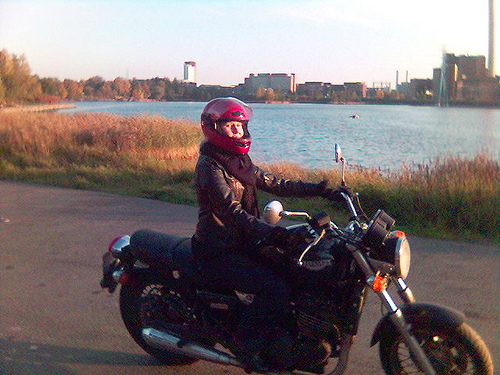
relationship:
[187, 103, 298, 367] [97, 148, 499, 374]
person on motorcycle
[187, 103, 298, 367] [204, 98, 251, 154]
person wears helmet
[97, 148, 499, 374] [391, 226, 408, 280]
motorcycle has headlight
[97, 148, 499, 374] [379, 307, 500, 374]
motorcycle has front tire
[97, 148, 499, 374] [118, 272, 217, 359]
motorcycle has rear tire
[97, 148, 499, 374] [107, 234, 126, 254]
motorcycle has brake light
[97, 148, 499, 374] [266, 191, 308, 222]
motorcycle has mirror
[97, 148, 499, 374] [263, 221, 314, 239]
motorcycle has handlebars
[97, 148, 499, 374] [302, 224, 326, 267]
motorcycle has turn signal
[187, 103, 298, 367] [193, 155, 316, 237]
person wears jacket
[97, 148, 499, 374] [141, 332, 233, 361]
motorcycle has exhaust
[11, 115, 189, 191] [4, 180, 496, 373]
grass near road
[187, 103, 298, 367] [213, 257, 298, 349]
person wears jeans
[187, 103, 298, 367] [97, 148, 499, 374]
person rides motorcycle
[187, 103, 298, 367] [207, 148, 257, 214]
person wears scarf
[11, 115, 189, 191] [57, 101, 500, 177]
grass near lake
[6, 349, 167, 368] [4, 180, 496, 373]
shadow on road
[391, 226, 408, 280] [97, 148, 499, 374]
headlight on motorcycle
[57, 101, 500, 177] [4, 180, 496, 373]
lake near road